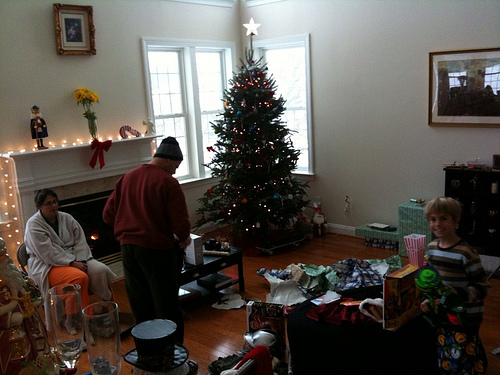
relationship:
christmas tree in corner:
[191, 11, 332, 246] [232, 11, 260, 77]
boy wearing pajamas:
[401, 189, 488, 364] [434, 315, 473, 372]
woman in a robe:
[20, 183, 120, 329] [26, 215, 116, 301]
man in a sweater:
[100, 123, 196, 364] [102, 155, 194, 257]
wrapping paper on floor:
[265, 246, 401, 298] [284, 245, 350, 264]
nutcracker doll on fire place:
[25, 98, 50, 150] [4, 132, 167, 296]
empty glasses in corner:
[38, 281, 135, 375] [2, 342, 66, 372]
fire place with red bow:
[4, 132, 167, 296] [85, 137, 110, 175]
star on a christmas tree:
[239, 13, 261, 39] [191, 11, 332, 246]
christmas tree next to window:
[191, 11, 332, 246] [144, 38, 226, 182]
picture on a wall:
[425, 47, 499, 130] [313, 13, 426, 198]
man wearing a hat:
[100, 123, 196, 364] [152, 136, 183, 165]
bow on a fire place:
[85, 137, 110, 175] [4, 132, 167, 296]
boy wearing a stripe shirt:
[401, 189, 488, 364] [416, 236, 493, 317]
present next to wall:
[351, 215, 399, 248] [313, 13, 426, 198]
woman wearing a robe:
[20, 183, 120, 329] [26, 215, 116, 301]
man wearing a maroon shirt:
[100, 123, 196, 364] [102, 155, 194, 257]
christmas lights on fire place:
[3, 129, 162, 174] [4, 132, 167, 296]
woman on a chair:
[20, 183, 120, 329] [14, 240, 27, 272]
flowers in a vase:
[71, 83, 97, 117] [83, 110, 101, 139]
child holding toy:
[401, 189, 488, 364] [412, 266, 459, 322]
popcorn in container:
[411, 233, 421, 241] [403, 229, 427, 273]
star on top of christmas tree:
[239, 13, 261, 39] [191, 11, 332, 246]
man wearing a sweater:
[100, 123, 196, 364] [102, 155, 194, 257]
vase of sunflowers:
[83, 110, 101, 139] [71, 83, 97, 117]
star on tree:
[239, 13, 261, 39] [191, 11, 332, 246]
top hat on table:
[117, 305, 195, 372] [184, 362, 197, 373]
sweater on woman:
[47, 220, 64, 242] [20, 183, 120, 329]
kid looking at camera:
[401, 189, 488, 364] [236, 215, 255, 241]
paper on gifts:
[404, 215, 416, 223] [394, 195, 433, 258]